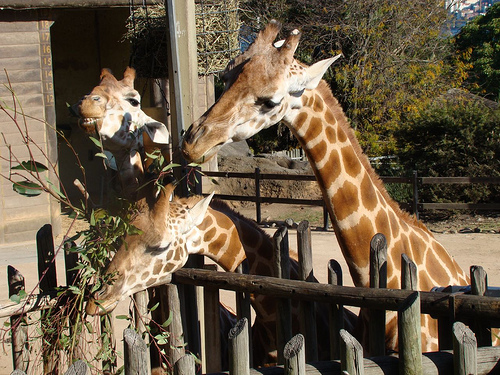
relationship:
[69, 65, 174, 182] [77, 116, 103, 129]
giraffe showing teeth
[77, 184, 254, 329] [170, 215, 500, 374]
giraffe leaning over corral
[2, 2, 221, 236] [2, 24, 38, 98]
building had siding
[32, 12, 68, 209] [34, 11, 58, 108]
frame has numbers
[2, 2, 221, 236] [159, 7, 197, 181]
building has frame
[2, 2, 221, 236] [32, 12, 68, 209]
building has frame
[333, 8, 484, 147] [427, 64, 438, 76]
leaves turning yellow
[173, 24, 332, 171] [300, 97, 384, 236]
giraffe has spots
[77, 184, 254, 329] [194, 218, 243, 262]
giraffe has spots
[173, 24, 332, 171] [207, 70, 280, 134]
giraffe has face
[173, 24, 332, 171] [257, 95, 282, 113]
giraffe has eye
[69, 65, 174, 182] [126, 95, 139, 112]
giraffe has eye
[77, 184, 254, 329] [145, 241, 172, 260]
giraffe has eye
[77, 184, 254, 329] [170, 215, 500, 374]
giraffe leans over corral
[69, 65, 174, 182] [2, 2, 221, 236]
giraffe beside building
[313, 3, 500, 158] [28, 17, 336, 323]
trees behind giraffes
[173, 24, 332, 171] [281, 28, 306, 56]
giraffe has horn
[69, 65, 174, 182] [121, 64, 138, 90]
giraffe has horn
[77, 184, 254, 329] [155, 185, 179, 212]
giraffe has horn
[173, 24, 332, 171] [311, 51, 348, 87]
giraffe has ear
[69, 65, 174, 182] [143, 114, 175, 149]
giraffe has ear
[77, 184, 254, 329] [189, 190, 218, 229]
giraffe has ear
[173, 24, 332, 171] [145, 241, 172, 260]
giraffe has eye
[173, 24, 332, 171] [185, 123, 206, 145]
giraffe has nose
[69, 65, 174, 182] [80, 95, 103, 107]
giraffe has nose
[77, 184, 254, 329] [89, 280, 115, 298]
giraffe has nose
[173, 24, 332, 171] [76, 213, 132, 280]
giraffe eats leaves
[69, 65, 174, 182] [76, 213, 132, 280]
giraffe eats leaves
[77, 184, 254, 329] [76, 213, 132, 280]
giraffe eats leaves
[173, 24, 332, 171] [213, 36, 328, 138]
giraffe has head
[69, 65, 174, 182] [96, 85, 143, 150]
giraffe has head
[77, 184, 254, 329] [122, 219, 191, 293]
giraffe has head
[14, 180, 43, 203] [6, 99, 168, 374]
leaf on tree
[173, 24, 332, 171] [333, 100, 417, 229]
giraffe has back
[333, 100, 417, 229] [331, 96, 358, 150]
back has comb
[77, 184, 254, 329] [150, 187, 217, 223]
giraffe has ears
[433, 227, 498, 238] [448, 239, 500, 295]
stumps on ground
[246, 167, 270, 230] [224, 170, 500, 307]
posts in corral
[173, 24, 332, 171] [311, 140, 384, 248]
giraffe has design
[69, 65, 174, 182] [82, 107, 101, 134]
giraffe has mouth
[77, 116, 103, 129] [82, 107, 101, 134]
teeth in mouth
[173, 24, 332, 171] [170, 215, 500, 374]
giraffe in corral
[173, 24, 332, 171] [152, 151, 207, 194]
giraffe eating grass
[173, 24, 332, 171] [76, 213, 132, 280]
giraffe munching on leaves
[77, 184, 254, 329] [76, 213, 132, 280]
giraffe munching on leaves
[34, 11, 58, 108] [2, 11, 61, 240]
numbers on wall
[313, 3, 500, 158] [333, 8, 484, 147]
tree has leaves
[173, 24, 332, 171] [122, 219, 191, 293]
giraffe looking at head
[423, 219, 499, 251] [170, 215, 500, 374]
rocks line corral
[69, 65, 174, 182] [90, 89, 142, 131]
giraffe has face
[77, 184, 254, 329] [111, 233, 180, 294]
giraffe has face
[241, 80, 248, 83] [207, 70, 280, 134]
light shines on face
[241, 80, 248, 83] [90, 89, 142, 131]
light shines on face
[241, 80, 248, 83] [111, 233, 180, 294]
light shines on face